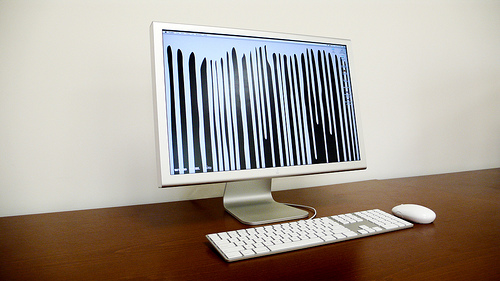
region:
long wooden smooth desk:
[7, 174, 497, 278]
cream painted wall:
[2, 2, 495, 219]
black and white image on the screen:
[164, 35, 366, 173]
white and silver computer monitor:
[147, 17, 367, 226]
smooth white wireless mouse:
[393, 201, 436, 223]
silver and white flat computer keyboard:
[200, 205, 410, 262]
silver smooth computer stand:
[222, 174, 311, 224]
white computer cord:
[276, 197, 320, 221]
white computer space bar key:
[265, 233, 322, 252]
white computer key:
[255, 246, 270, 255]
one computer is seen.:
[130, 20, 440, 261]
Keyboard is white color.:
[190, 220, 395, 270]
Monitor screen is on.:
[135, 20, 370, 180]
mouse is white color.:
[380, 180, 440, 240]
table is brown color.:
[50, 220, 145, 260]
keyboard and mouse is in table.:
[206, 215, 471, 255]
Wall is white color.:
[385, 25, 465, 126]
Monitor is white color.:
[125, 15, 412, 215]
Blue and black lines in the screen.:
[171, 35, 347, 141]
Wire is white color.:
[292, 196, 322, 222]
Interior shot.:
[3, 4, 498, 276]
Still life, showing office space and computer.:
[18, 10, 484, 277]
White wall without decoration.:
[9, 27, 121, 172]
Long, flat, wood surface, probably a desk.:
[23, 219, 179, 268]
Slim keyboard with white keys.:
[201, 202, 417, 260]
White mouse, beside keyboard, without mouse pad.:
[395, 199, 435, 228]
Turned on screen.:
[166, 34, 358, 161]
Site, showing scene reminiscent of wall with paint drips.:
[173, 40, 333, 157]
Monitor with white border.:
[132, 30, 381, 184]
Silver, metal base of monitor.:
[225, 182, 312, 221]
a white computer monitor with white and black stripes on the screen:
[137, 12, 387, 205]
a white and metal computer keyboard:
[197, 198, 417, 269]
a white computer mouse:
[385, 191, 441, 231]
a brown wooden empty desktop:
[21, 220, 178, 279]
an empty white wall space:
[17, 29, 138, 159]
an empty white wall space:
[370, 26, 495, 153]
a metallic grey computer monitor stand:
[213, 184, 318, 226]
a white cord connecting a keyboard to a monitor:
[282, 195, 329, 222]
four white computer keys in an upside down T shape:
[355, 219, 386, 239]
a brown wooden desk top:
[396, 237, 498, 279]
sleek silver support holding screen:
[177, 176, 317, 226]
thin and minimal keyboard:
[201, 195, 406, 262]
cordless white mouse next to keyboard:
[362, 195, 444, 230]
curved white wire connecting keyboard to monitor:
[266, 196, 321, 217]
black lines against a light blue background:
[161, 25, 361, 180]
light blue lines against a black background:
[141, 19, 372, 177]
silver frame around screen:
[140, 15, 366, 190]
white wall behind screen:
[57, 5, 387, 185]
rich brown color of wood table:
[81, 176, 451, 261]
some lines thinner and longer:
[148, 28, 358, 168]